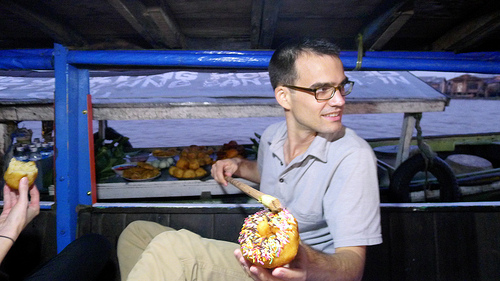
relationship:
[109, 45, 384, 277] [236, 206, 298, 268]
man holding donut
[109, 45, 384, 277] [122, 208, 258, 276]
man wearing khaki pant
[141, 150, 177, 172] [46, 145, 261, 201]
tray on table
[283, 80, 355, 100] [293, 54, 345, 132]
glasses on face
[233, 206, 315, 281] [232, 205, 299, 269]
hand holding donut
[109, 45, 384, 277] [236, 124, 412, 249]
man has shirt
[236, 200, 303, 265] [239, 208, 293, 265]
donut has sprinkles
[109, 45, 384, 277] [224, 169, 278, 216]
man has hand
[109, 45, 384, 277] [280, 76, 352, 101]
man wearing glasses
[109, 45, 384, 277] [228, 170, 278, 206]
man holding stick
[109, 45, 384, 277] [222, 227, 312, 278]
man has hand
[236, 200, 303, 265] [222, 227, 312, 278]
donut in hand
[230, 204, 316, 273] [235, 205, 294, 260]
hand holding donut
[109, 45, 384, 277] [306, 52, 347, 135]
man has face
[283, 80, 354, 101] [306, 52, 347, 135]
glasses on face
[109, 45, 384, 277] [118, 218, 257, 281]
man wearing khaki pant